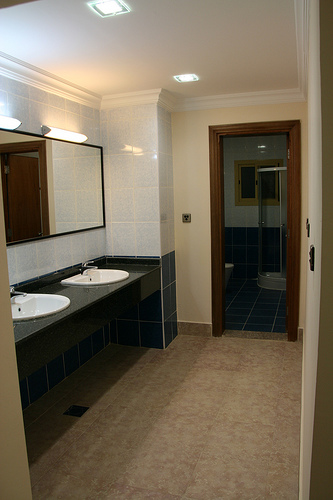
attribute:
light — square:
[93, 0, 119, 17]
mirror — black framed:
[2, 132, 105, 236]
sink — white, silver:
[69, 263, 126, 285]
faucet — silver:
[82, 262, 102, 274]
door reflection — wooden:
[6, 146, 47, 230]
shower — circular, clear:
[256, 171, 288, 287]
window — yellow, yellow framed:
[241, 167, 271, 199]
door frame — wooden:
[207, 123, 236, 335]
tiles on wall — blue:
[108, 299, 180, 338]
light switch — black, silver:
[182, 212, 192, 222]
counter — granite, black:
[10, 269, 154, 325]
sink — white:
[9, 297, 74, 309]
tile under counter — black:
[26, 350, 94, 396]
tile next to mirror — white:
[97, 113, 168, 254]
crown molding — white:
[91, 93, 174, 105]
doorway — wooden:
[208, 121, 303, 337]